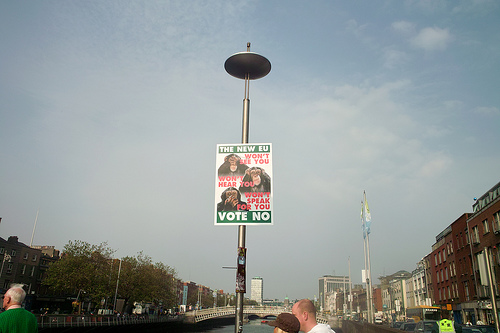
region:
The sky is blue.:
[0, 0, 498, 299]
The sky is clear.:
[0, 0, 498, 300]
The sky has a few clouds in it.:
[0, 0, 497, 298]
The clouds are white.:
[387, 15, 452, 55]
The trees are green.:
[41, 240, 176, 317]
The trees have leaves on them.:
[39, 242, 181, 311]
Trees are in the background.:
[43, 242, 181, 316]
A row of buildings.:
[0, 213, 265, 313]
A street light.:
[221, 39, 268, 331]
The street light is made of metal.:
[221, 37, 271, 329]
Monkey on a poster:
[247, 162, 267, 188]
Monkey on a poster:
[223, 188, 239, 210]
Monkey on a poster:
[221, 156, 243, 183]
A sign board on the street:
[196, 132, 278, 323]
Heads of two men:
[266, 302, 342, 331]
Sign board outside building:
[361, 188, 380, 331]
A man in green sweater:
[3, 289, 36, 331]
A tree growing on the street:
[37, 244, 182, 317]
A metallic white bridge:
[196, 301, 236, 331]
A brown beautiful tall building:
[426, 217, 483, 299]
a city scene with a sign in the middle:
[14, 14, 486, 324]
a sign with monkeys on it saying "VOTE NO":
[208, 137, 280, 234]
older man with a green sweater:
[1, 285, 34, 327]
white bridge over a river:
[190, 302, 293, 323]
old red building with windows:
[422, 232, 454, 307]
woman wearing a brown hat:
[265, 314, 302, 331]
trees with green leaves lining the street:
[50, 247, 177, 306]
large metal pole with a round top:
[228, 36, 252, 331]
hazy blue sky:
[10, 11, 201, 232]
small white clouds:
[358, 13, 462, 64]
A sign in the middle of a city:
[24, 32, 492, 327]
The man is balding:
[4, 282, 33, 309]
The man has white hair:
[10, 290, 20, 303]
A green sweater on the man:
[7, 312, 39, 332]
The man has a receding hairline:
[286, 295, 317, 322]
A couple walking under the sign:
[267, 290, 338, 331]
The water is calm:
[232, 320, 264, 330]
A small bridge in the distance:
[200, 301, 290, 321]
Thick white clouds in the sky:
[273, 102, 366, 198]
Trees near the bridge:
[49, 244, 179, 324]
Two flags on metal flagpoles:
[352, 190, 380, 240]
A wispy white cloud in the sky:
[392, 21, 454, 63]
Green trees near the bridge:
[58, 246, 175, 308]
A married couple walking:
[268, 298, 329, 331]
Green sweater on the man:
[1, 307, 40, 332]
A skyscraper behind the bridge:
[250, 276, 270, 305]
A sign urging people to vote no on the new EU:
[211, 138, 282, 223]